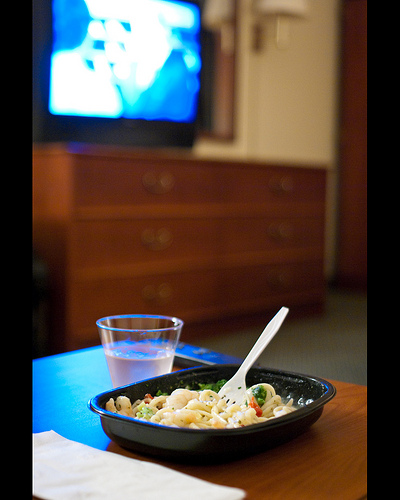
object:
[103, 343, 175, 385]
drink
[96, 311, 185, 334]
edge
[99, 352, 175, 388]
water level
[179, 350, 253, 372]
part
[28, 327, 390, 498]
part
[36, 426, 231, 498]
white cloth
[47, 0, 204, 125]
television screen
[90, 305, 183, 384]
cup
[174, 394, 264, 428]
noodles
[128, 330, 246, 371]
remote control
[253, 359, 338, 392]
edge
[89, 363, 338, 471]
black bowl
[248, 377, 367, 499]
brown table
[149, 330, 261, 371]
remote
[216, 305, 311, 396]
white fork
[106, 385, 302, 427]
food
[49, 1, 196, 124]
television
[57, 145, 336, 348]
dresser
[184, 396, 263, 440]
pasta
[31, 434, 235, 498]
napkin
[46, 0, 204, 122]
tv is turned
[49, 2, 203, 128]
tv is setting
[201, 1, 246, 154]
mirror is behind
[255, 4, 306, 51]
lamp on wall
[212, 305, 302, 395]
fork in pasta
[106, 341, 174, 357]
ice in drink